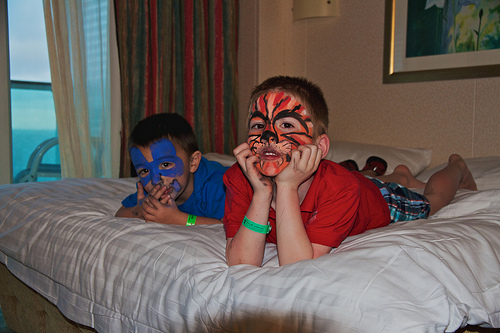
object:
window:
[6, 0, 100, 88]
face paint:
[126, 138, 188, 194]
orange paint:
[307, 126, 312, 131]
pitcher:
[380, 1, 500, 85]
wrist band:
[183, 212, 196, 228]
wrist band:
[239, 214, 273, 235]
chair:
[10, 133, 104, 187]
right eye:
[247, 121, 265, 130]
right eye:
[137, 165, 151, 178]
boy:
[220, 75, 478, 268]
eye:
[278, 120, 297, 130]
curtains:
[43, 0, 124, 182]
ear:
[188, 149, 203, 174]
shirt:
[220, 157, 393, 248]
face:
[243, 89, 316, 178]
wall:
[306, 1, 500, 170]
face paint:
[243, 89, 315, 175]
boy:
[112, 111, 227, 228]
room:
[1, 0, 499, 332]